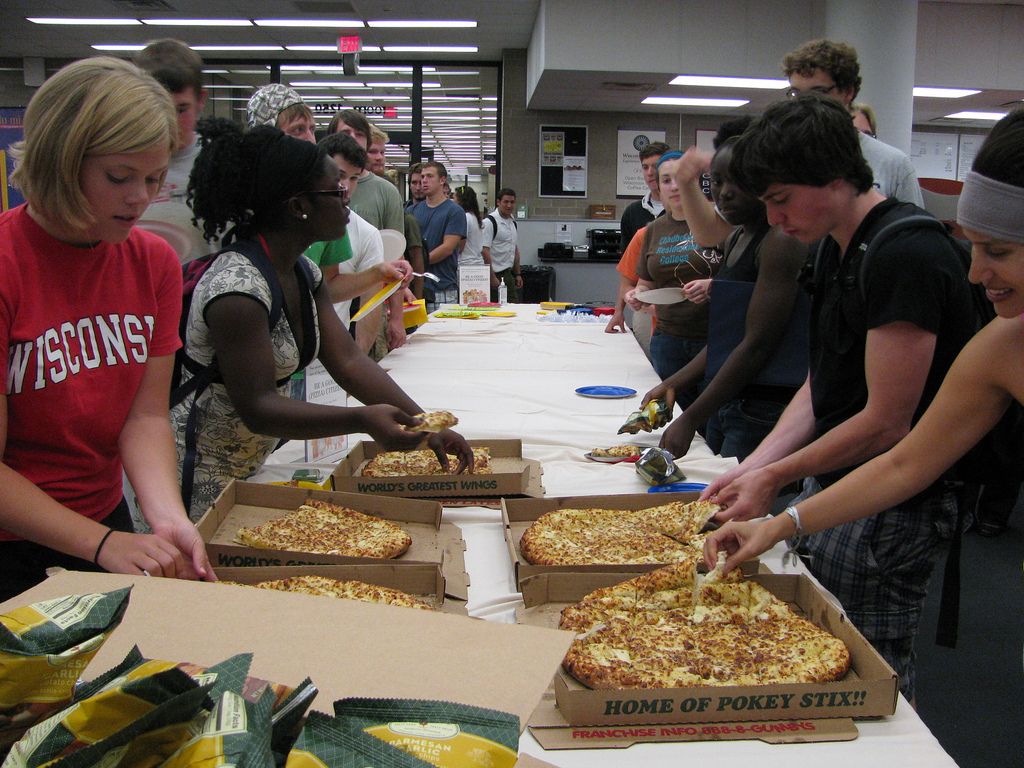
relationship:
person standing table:
[8, 55, 225, 568] [6, 320, 933, 748]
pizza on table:
[211, 399, 924, 758] [71, 248, 973, 765]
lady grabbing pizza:
[686, 96, 1022, 764] [520, 537, 899, 756]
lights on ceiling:
[26, 10, 498, 190] [10, 12, 1022, 218]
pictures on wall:
[533, 120, 689, 209] [501, 51, 759, 293]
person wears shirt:
[0, 56, 221, 608] [2, 224, 199, 518]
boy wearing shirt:
[299, 133, 364, 276] [295, 222, 352, 272]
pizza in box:
[556, 569, 850, 695] [509, 578, 888, 736]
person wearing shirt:
[480, 188, 521, 304] [475, 212, 521, 271]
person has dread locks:
[0, 56, 221, 608] [187, 115, 327, 246]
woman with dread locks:
[166, 123, 456, 521] [188, 108, 318, 260]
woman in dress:
[166, 123, 456, 521] [154, 254, 336, 555]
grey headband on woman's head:
[948, 150, 1016, 244] [933, 89, 1020, 325]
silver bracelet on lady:
[786, 487, 808, 570] [699, 102, 1024, 572]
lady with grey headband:
[699, 102, 1024, 572] [950, 141, 1017, 228]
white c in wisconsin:
[56, 320, 89, 375] [14, 297, 164, 414]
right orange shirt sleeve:
[585, 187, 672, 298] [614, 226, 641, 279]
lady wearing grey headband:
[699, 102, 1024, 572] [955, 171, 1024, 245]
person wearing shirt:
[625, 143, 718, 342] [633, 219, 718, 315]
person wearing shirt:
[478, 188, 528, 288] [482, 215, 528, 283]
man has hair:
[742, 107, 954, 417] [774, 122, 844, 162]